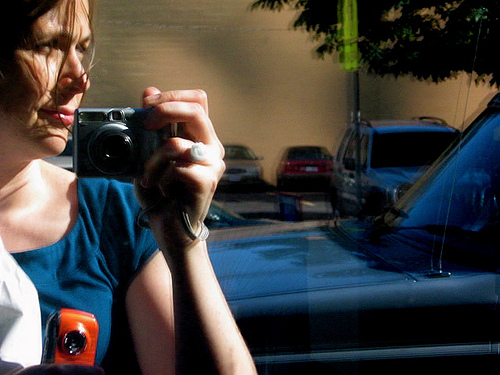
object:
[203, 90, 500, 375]
black vehicle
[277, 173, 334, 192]
black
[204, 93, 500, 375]
vehicle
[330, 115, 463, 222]
vehicle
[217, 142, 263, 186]
vehicle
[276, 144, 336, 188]
vehicle